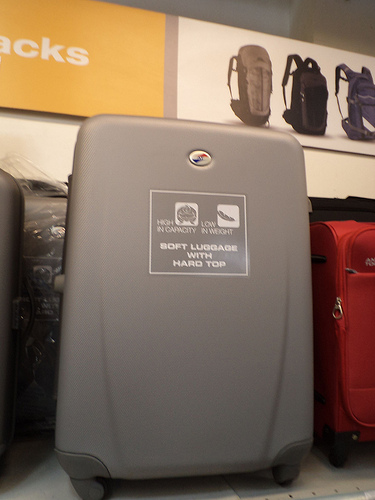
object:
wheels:
[323, 449, 349, 469]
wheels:
[78, 477, 113, 499]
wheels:
[271, 466, 297, 491]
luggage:
[51, 112, 317, 497]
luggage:
[311, 219, 375, 467]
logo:
[186, 147, 215, 169]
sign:
[3, 0, 164, 118]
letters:
[0, 32, 92, 67]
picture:
[176, 17, 374, 156]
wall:
[2, 2, 374, 197]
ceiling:
[111, 1, 373, 53]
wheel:
[76, 476, 113, 498]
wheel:
[274, 464, 297, 484]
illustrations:
[226, 43, 274, 128]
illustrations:
[281, 52, 329, 137]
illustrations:
[334, 61, 374, 142]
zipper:
[331, 298, 344, 318]